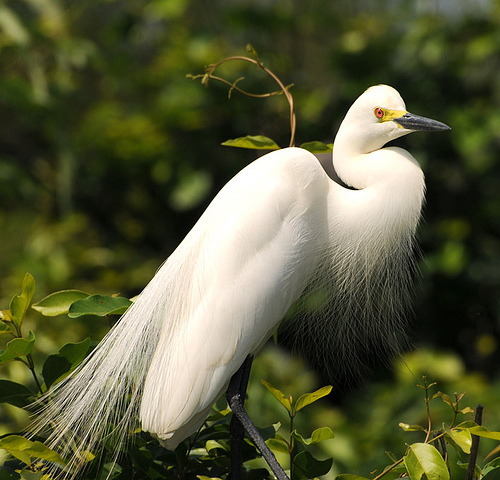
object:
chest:
[263, 178, 325, 305]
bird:
[23, 82, 450, 480]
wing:
[140, 150, 285, 442]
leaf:
[32, 289, 88, 315]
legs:
[226, 350, 290, 479]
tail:
[18, 301, 152, 479]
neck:
[324, 146, 428, 250]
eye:
[373, 106, 384, 119]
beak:
[397, 113, 451, 135]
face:
[371, 92, 453, 135]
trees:
[1, 1, 498, 479]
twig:
[184, 44, 295, 150]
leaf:
[221, 135, 279, 149]